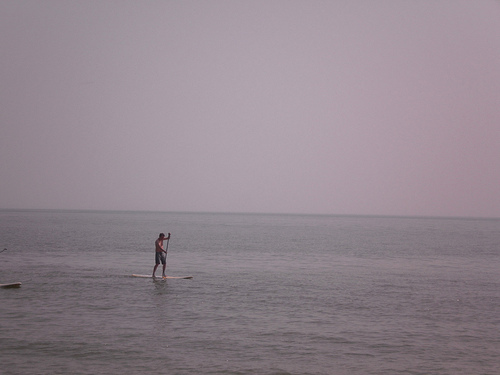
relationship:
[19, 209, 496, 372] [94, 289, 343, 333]
ocean has waves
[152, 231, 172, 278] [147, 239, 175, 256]
male not wearing a shirt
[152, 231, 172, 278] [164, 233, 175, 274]
male holding paddle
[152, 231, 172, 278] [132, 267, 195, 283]
male on a board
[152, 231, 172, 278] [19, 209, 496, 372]
male in ocean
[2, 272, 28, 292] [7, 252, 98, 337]
object in water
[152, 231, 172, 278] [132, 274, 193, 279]
male on a board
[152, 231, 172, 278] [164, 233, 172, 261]
male holding paddle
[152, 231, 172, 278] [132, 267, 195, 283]
male standing on a board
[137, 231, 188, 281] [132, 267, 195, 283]
person standing on a board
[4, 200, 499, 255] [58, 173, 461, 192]
horizon in distance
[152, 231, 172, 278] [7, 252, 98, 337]
male on water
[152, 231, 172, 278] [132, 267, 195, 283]
male standing on a surfboard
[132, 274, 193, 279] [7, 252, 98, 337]
board in water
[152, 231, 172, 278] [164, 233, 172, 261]
male holding onto a paddle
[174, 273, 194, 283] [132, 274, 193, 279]
front part of a board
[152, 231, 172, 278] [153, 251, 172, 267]
male wearing shorts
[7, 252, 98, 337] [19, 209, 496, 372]
water in ocean